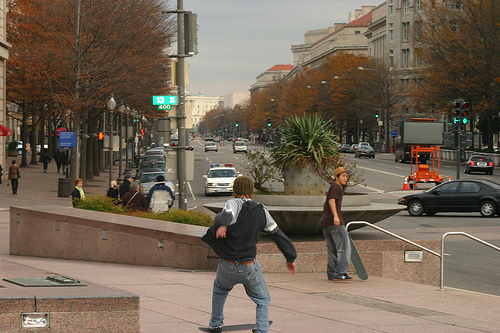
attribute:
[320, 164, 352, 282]
man — young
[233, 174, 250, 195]
hair — brown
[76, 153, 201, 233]
group — small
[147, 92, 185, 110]
street sign — green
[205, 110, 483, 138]
lights — green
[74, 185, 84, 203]
scarf — bright, green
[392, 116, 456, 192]
construction sign — caution sign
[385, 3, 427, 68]
building — tall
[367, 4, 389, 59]
building — tall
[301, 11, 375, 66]
building — tall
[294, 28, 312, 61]
building — tall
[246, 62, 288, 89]
building — tall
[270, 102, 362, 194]
bush — odd looking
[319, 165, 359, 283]
man — young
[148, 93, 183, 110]
street signs — green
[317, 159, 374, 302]
man — young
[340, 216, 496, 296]
railings — silver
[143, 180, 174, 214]
jacket — black, white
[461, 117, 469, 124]
light — green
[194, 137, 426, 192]
roadway — wide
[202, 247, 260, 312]
blue jeans — baggy